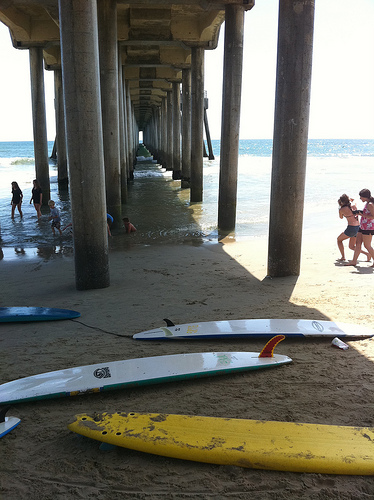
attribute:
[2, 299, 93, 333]
surfboard — blue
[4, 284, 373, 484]
surfboards — group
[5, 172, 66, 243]
people — standing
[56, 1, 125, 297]
post — concrete, support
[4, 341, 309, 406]
surfboard — white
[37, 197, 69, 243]
child — playing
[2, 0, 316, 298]
dock — underside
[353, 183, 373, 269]
girl — brown haired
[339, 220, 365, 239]
shorts — pair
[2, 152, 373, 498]
beach — sandy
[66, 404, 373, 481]
surfboard — yellow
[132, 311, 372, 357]
surfboard — white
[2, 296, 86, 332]
surfboard — blue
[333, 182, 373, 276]
women — walking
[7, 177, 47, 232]
women — standing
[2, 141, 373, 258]
water — ocean, large body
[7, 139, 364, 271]
water — ocean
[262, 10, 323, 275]
plyon — support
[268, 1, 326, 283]
pillar — tall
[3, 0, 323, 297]
pier — beach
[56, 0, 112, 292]
pillar — tall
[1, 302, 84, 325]
surfboard — blue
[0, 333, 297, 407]
surfboard — white